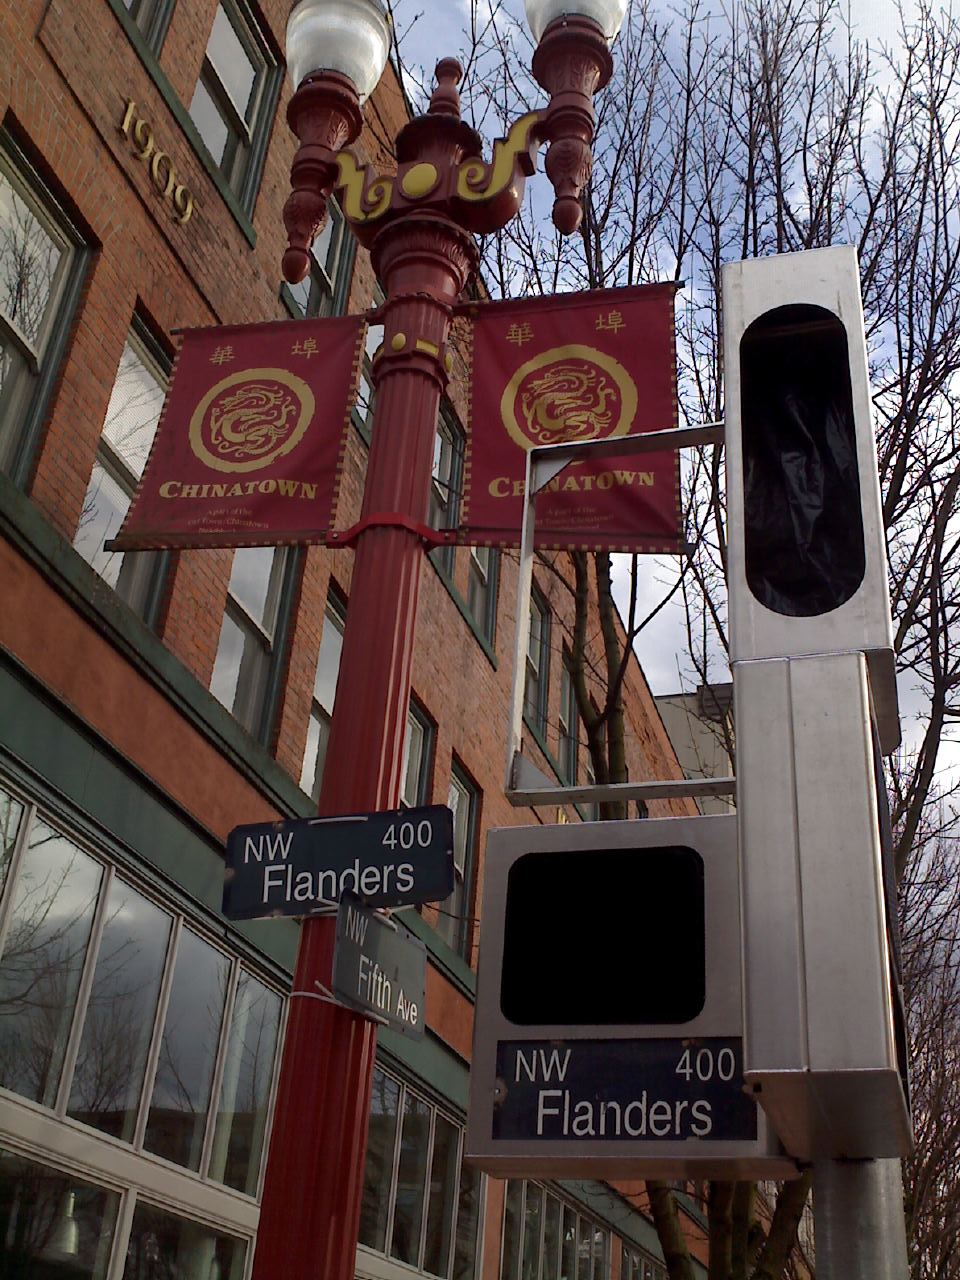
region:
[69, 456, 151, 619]
glass window on the building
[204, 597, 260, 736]
glass window on the building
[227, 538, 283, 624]
glass window on the building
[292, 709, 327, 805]
glass window on the building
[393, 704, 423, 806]
glass window on the building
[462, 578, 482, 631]
glass window on the building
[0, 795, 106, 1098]
glass window on the building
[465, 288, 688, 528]
red banner on the pole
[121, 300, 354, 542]
red banner on the pole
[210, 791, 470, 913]
traffic sign is blue and white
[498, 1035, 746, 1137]
traffic sign is blue and white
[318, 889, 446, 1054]
traffic sign is blue and white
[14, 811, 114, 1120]
Window on the building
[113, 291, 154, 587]
Window on the building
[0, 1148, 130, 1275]
Window on the building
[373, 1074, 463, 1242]
Window on the building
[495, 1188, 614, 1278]
Window on the building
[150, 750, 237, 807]
brown color on the wall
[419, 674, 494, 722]
red and black bricks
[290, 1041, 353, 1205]
deep red color on the post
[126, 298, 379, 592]
red and gold flag on pole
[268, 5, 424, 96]
frosted white lamp on pole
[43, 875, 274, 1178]
large window glass pane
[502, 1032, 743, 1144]
white words on light pole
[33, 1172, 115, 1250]
white bell in the window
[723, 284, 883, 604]
shiny black plastic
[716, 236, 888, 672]
black plastic oval inside rectangular metal box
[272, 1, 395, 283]
red fixture with glazed glass lamp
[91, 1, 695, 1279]
red and gold lamppost with red chinatown banners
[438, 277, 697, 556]
red and gold banner with dragon logo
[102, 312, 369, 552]
red and gold banner with dragon logo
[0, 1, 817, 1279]
orange and green building with number 1909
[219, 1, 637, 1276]
two black street signs attached to red lamppost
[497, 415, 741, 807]
empty silver metal frame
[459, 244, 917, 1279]
silver rectangular pole with black street sign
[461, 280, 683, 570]
red banner on the pole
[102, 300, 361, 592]
red banner on the pole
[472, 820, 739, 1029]
electric sign on the pole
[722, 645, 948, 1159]
electric sign on the pole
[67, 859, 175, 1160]
a window on a building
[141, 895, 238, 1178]
a window on a building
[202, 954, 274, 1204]
a window on a building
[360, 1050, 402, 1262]
a window on a building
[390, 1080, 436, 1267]
a window on a building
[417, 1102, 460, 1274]
a window on a building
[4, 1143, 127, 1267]
a window on a building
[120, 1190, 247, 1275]
a window on a building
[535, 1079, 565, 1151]
a letter on a sign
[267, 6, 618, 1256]
street lamps on a post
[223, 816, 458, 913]
black sign with white lettering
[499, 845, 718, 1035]
electronic display turned off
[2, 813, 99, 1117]
tree reflecting in a window pane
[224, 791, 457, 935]
a sign on a red pole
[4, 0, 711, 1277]
the building facade is made of brick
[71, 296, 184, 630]
the window has green trim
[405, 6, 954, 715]
a tree without leaves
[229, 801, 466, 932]
sign on the pole is blue and white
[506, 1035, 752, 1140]
sign on the pole is blue and white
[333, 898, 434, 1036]
sign on the pole is blue and white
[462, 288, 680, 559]
red banner on the pole